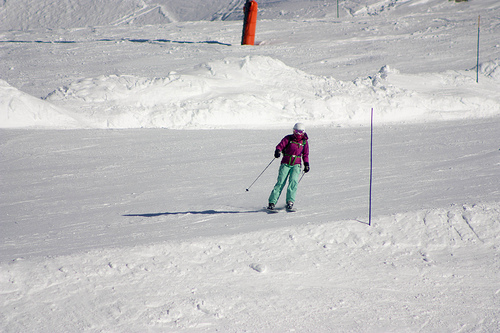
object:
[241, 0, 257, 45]
pole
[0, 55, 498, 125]
snow clump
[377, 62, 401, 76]
clump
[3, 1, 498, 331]
slope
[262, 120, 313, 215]
person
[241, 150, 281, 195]
ski pole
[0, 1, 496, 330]
snow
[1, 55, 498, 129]
clump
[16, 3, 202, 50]
snow/hillside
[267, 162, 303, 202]
pants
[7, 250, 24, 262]
clump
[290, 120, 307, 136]
white helmet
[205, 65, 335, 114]
clump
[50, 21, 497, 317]
hill side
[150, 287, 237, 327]
snow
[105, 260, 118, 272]
clump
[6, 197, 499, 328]
slope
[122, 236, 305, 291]
snow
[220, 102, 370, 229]
skiing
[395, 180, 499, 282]
snow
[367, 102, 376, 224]
pole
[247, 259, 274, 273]
clump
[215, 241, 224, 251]
clump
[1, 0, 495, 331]
ski slope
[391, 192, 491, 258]
clump